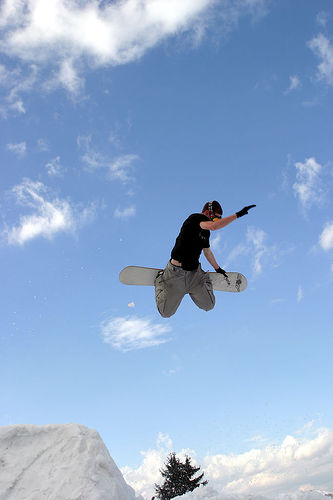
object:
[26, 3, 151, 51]
clouds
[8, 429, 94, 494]
snow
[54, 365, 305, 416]
sky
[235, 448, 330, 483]
clouds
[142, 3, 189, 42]
clouds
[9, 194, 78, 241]
clouds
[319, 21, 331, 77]
clouds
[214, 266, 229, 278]
gloves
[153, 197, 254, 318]
man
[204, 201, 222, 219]
goggles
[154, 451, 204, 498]
tree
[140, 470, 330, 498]
snow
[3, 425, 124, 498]
snow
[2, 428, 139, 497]
snow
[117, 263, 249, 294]
snowboard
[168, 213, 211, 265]
shirt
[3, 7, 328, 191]
sky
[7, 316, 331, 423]
sky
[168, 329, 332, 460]
sky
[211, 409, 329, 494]
sky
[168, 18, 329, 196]
sky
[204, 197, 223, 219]
head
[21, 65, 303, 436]
sky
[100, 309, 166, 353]
clouds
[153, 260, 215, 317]
pants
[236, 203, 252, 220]
gloves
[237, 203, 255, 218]
hands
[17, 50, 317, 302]
sky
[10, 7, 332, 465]
photo